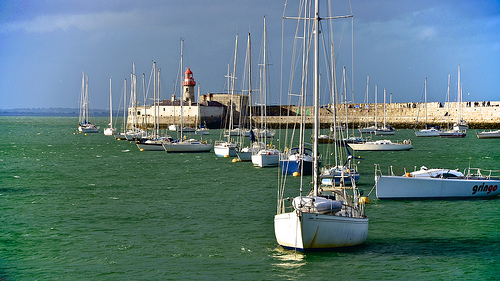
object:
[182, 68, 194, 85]
lighthouse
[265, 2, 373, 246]
ships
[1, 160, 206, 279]
water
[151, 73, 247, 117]
building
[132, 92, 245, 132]
stone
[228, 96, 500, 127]
walkway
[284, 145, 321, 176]
sailboat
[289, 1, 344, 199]
masts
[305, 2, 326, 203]
metal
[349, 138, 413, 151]
boat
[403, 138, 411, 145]
motor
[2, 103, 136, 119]
mountains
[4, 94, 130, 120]
distance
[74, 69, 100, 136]
boats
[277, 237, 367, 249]
rust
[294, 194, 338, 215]
raft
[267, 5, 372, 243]
boat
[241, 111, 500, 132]
wall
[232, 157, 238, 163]
bouys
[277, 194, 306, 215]
rail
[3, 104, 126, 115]
hills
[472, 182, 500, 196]
gringo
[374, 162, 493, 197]
boat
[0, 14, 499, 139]
background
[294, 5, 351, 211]
sails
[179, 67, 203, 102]
light house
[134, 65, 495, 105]
back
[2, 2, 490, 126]
clouds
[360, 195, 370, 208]
anchors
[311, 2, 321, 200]
pole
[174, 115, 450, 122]
people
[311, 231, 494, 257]
shadow